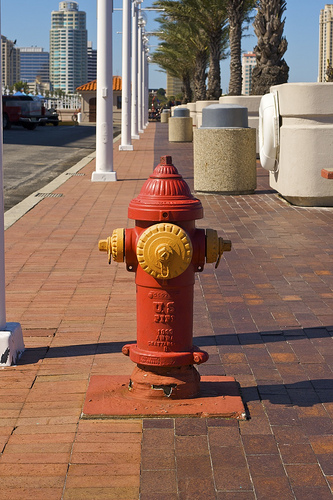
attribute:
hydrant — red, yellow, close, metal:
[106, 132, 241, 412]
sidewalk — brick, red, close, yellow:
[39, 184, 107, 364]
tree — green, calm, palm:
[166, 7, 276, 97]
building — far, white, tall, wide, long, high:
[41, 6, 90, 87]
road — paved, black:
[26, 121, 79, 180]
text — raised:
[150, 299, 173, 345]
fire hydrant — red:
[74, 151, 250, 421]